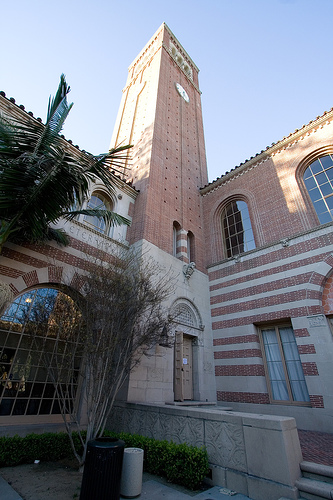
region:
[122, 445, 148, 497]
white cement ash tray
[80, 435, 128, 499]
round black metal trash can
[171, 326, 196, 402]
light brown panel open door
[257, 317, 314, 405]
paneled window with brown trim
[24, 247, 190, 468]
skinny tree with no leaves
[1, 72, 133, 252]
top of a bright green palm tree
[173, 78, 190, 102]
round white clock face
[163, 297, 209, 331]
half circle decorative window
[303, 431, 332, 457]
small section of red brick sidewalk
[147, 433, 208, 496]
bright green hedge row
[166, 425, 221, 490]
bushes on a street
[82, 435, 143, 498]
a black garbage can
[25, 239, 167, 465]
tree on a street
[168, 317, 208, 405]
entrance to a building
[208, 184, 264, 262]
windows of a building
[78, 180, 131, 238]
windows of a building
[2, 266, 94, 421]
reflections from the window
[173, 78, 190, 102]
clock on a building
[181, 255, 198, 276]
a statue on a building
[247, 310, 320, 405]
window with a curtain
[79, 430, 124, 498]
a black trashcan outside a building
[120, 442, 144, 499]
a white cigarette receptacle next to a trashcan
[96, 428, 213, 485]
a shrub alongside a wall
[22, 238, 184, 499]
a tree beside a trashcan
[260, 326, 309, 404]
a white curtain inside a window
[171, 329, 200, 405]
an open light brown double door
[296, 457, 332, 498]
concrete steps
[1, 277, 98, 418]
a large arched window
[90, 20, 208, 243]
a tower on a building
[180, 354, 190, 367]
a paper attached to the outside of a door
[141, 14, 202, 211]
pink clock tower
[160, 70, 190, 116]
clock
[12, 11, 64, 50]
white clouds n blue sky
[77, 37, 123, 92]
white clouds n blue sky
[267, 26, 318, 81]
white clouds n blue sky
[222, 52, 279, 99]
white clouds n blue sky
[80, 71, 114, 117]
white clouds n blue sky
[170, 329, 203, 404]
A doorway to the building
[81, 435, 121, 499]
A black trash can outside the building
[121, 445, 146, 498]
A white cigarette tray stand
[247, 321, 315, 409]
A long window in the building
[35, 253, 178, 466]
A tree located next to the building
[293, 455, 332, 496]
Stairs leading up to the entrance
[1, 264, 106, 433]
A big window in the building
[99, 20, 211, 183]
The clock tower of the building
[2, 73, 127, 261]
The top of a palm tree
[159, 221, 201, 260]
Two smaller windows above the entrance